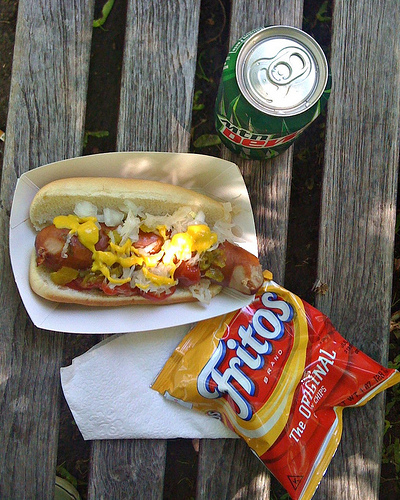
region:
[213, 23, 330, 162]
a can of Mountain Dew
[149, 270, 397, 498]
a bag of Fritos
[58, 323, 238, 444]
a white napkin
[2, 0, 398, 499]
a wooden bench seat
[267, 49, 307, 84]
a tab on a soda can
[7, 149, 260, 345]
a paper hotdog holder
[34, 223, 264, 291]
a hotdog in a bun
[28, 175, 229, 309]
a hotdog bun holding a hotdog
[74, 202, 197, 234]
onions on a hotdog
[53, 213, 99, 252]
mustard on a hotdog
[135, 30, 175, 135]
A wooden bench piece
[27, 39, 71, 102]
Worn out piece of wood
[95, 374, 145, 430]
A paper napking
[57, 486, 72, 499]
Shoe between the space on the bench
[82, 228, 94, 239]
Mustard on a roll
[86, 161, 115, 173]
The inside of a paper plate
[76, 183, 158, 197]
A roll of bread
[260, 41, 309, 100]
The top of a can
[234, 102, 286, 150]
A can on the bench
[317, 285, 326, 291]
Wood on the bench chipped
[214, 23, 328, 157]
a can of soda on a plank of wood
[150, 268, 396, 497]
a bag of chips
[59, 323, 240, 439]
a white folded paper towel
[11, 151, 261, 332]
a white paper tray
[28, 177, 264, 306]
a hot dog in a white paper tray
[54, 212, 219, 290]
yellow mustard on a hot dog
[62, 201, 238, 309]
bits of white onions on a hot dog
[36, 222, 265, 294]
a cooked wiener in a hot dog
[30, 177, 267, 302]
a hot dog with onion, mustard and ketchup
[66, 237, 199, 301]
ketchup on a hot dog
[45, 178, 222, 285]
a delicious looking burgar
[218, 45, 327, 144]
A energy drink in a can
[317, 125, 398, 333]
A grey bench wood timber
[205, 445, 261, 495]
A grey bench wood timber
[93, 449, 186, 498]
A grey bench wood timber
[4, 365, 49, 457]
A grey bench wood timber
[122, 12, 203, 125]
A grey bench wood timber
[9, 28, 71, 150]
A grey bench wood timber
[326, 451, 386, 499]
A grey bench wood timber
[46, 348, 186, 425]
A white servriete cloth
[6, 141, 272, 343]
The hotdog is on a bun.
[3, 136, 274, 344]
The hotdog is in a cardboard container.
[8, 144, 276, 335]
The hotdog has mustard on it.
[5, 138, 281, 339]
The hotdog has ketchup on it.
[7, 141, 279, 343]
The hotdog has relish on it.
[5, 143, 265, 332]
The hotdog has onions on it.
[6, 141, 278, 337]
The hotdog has saurkraut on it.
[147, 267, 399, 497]
The Fritos are unopened.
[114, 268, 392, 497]
The Fristos are sitting on the table.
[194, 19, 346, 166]
The Mountain Dew is unopened.